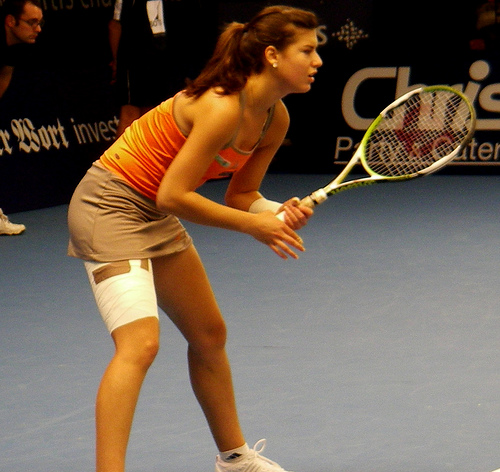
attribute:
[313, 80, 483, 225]
racket — green, white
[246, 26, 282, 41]
hair — brown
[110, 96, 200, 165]
shirt — orange, sleeve less, gray, wrinkled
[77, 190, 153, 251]
skirt — brown, wrinkled, short, grey, tan, beige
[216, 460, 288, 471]
shoe — white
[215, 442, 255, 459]
sock — white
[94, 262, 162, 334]
wrap — white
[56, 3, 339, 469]
woman — bending, playing, consentrating, tennis player, tan, waiting, playing tennis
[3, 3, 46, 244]
man — leaning, watching, serious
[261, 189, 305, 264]
grip — two-hand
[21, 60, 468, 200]
sign — english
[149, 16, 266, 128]
pony tail — brown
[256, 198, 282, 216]
wristband — taped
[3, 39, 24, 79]
shirt — dark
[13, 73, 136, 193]
ad — black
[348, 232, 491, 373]
court — gray, clean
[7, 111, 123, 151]
words — white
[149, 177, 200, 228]
elbow — bent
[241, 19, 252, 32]
band — brown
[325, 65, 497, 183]
banner — big, white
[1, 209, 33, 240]
shoe — white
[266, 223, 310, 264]
fingers — extended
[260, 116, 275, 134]
strap — gray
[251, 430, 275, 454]
lace — white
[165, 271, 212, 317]
thigh — tan